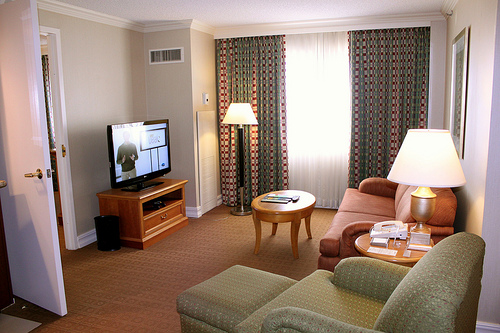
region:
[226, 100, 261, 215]
a tall lamp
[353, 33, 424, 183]
curtains on the window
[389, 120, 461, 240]
a lamp sitting on a table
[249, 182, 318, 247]
a coffee table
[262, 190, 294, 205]
books on the table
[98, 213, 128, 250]
a trash can on the floor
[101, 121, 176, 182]
a television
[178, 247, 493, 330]
a green chair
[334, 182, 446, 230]
a red sofa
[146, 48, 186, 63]
the vent in the wall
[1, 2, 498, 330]
a living room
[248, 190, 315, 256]
an oval shaped wooden table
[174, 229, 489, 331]
a brown colored chair and ottoman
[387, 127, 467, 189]
a white lamp shade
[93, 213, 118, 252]
a black garbage can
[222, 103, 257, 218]
a tall illuminated lamp with a white shade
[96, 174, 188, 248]
a wooden TV stand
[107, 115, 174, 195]
a flat screen TV with a black housing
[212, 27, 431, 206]
a window covered by curtains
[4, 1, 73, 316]
an open door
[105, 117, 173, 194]
Flat screen television turned on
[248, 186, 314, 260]
Small round wooden coffee table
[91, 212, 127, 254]
Small black trash can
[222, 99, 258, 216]
Black floor lamp with white lamp shade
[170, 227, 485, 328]
Green single person sofa chair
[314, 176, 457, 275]
Orange two person sofa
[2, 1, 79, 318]
An opened door in a room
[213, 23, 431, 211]
Red and green ceiling high window curtains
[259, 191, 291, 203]
Magazine on a coffee table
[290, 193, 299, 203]
Remote control on a coffee table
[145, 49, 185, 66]
Heating and cooling vent in wall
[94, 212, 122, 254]
Black circular waste can without liner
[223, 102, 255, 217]
Silver and black floor lamp with white shade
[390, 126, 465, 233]
Brushed silver table lamp with white shade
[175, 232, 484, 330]
Green with white dots low back upholstered chair and ottoman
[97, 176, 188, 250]
Wood television stand with one lower shelf and one drawer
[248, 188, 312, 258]
Wood oval coffee table, no shelves, curved legs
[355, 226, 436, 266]
Round wood end table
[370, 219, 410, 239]
White corded phone sitting on table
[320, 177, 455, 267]
Tan leather-like low back sofa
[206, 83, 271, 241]
floor lamp on the floor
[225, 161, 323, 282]
oval wooden table in living room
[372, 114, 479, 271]
big lamp on table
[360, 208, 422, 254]
white telephone on table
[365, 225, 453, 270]
papers on table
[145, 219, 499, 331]
green couch in living room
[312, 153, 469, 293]
brown couch in living room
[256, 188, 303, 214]
books on top of table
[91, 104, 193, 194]
flat screen tv on table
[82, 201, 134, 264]
black garbage can next to cabinet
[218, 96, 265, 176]
Lamp is turned on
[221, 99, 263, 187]
Lamp is turned on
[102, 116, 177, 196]
Television is turned on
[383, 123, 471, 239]
Lamp is turned on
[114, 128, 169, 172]
Screen of a television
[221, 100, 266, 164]
Lamp is turned on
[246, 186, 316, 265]
a brown coffee table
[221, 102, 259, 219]
a white and black standing lamp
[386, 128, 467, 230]
a white and brown lamp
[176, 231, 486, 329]
a green couch with a foot stool